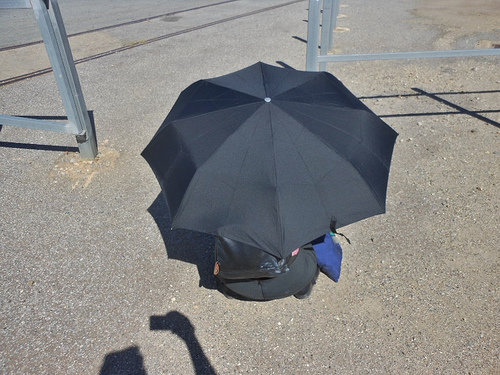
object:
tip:
[239, 83, 292, 118]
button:
[262, 95, 274, 104]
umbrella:
[136, 60, 399, 259]